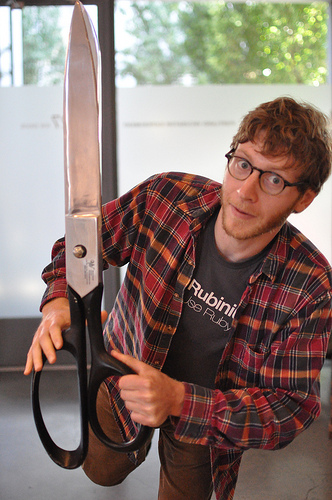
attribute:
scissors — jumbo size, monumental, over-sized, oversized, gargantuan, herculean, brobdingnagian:
[23, 0, 157, 478]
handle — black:
[24, 284, 147, 480]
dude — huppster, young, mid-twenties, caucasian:
[18, 91, 331, 499]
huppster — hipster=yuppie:
[15, 87, 329, 500]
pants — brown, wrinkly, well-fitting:
[71, 354, 222, 500]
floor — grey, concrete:
[0, 356, 331, 496]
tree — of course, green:
[180, 0, 331, 83]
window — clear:
[1, 1, 331, 87]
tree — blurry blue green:
[112, 1, 213, 87]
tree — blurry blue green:
[21, 6, 66, 83]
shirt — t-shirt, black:
[157, 203, 284, 389]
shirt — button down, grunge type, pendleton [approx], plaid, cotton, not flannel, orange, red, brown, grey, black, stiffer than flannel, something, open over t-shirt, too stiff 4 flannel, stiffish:
[34, 167, 331, 499]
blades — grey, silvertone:
[58, 0, 111, 303]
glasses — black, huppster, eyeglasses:
[225, 145, 309, 199]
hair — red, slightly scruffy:
[224, 91, 330, 200]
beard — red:
[212, 184, 302, 248]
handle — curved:
[29, 282, 89, 474]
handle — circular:
[84, 282, 147, 464]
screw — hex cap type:
[70, 243, 91, 263]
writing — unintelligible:
[82, 254, 96, 291]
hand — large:
[15, 296, 113, 378]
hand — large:
[104, 343, 183, 432]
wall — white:
[4, 84, 331, 319]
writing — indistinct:
[14, 107, 254, 135]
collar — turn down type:
[172, 182, 292, 289]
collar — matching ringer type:
[207, 210, 278, 268]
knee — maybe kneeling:
[80, 400, 152, 491]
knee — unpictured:
[153, 494, 217, 498]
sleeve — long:
[173, 219, 330, 456]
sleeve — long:
[32, 167, 221, 309]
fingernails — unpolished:
[18, 338, 65, 377]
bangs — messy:
[233, 118, 312, 175]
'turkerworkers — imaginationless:
[0, 493, 12, 499]